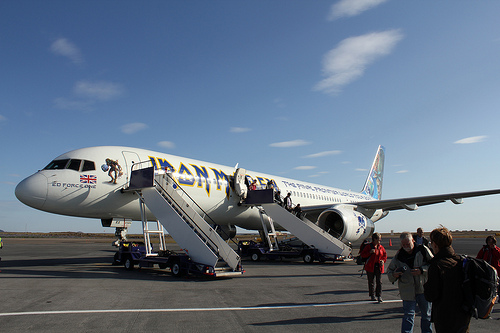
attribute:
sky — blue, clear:
[113, 54, 149, 92]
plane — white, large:
[27, 129, 485, 221]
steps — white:
[142, 178, 231, 272]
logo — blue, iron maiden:
[180, 165, 217, 184]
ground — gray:
[24, 285, 57, 296]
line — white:
[112, 306, 135, 319]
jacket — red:
[362, 246, 384, 266]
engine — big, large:
[334, 207, 365, 243]